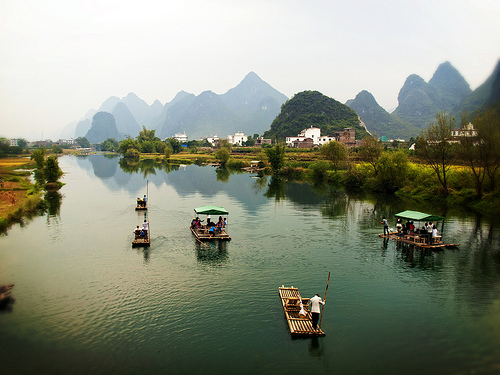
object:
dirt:
[0, 190, 28, 217]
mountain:
[155, 89, 249, 146]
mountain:
[220, 70, 292, 143]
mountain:
[262, 89, 376, 146]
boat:
[276, 284, 328, 339]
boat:
[374, 210, 461, 249]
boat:
[187, 205, 232, 248]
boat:
[134, 190, 149, 212]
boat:
[131, 221, 152, 250]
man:
[379, 216, 388, 238]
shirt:
[380, 218, 390, 226]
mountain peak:
[395, 74, 440, 107]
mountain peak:
[425, 59, 465, 88]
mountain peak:
[395, 86, 427, 104]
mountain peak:
[346, 89, 386, 114]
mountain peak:
[278, 90, 336, 110]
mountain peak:
[147, 97, 165, 111]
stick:
[145, 178, 150, 210]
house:
[295, 138, 315, 150]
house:
[338, 125, 355, 140]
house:
[283, 122, 337, 148]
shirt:
[306, 297, 327, 315]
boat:
[130, 213, 152, 250]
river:
[0, 151, 499, 374]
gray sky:
[0, 0, 498, 142]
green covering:
[190, 204, 233, 216]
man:
[305, 292, 327, 330]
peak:
[237, 71, 265, 84]